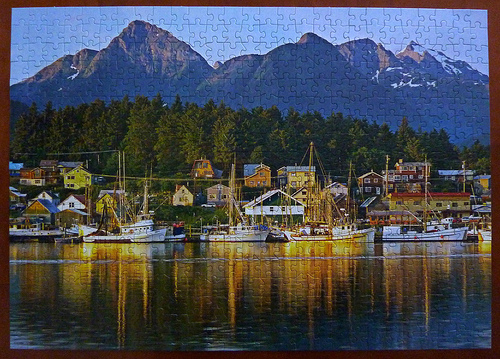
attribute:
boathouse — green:
[243, 184, 310, 230]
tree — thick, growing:
[111, 101, 153, 179]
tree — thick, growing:
[152, 104, 185, 174]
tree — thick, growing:
[202, 104, 247, 168]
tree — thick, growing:
[264, 118, 298, 163]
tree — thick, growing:
[38, 99, 66, 154]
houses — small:
[239, 158, 486, 198]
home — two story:
[245, 162, 272, 189]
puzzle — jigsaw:
[7, 9, 494, 354]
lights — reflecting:
[8, 239, 489, 348]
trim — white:
[241, 187, 307, 227]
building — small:
[57, 161, 96, 191]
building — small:
[15, 160, 56, 189]